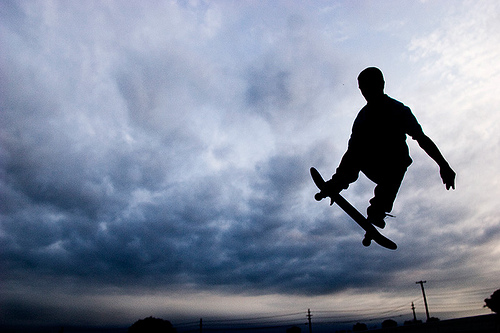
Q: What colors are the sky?
A: Blue, white, and grey.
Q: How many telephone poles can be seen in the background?
A: Four.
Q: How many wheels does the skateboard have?
A: Two.